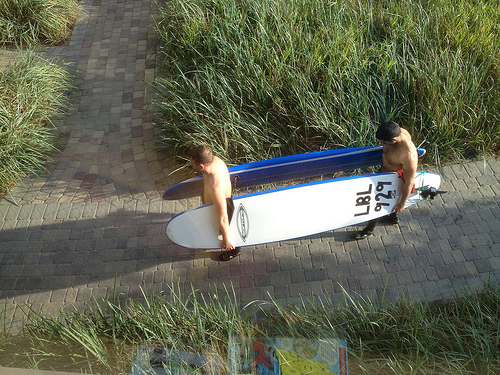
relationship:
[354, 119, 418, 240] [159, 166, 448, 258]
fellas with surfboards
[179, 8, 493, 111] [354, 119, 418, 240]
grass right fellas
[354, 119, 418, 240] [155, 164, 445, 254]
fellas hold surf boards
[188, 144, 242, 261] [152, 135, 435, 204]
dudes hold surf boards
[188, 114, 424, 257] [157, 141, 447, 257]
dudes hold surf boards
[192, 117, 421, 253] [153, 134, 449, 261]
fellas hold surf boards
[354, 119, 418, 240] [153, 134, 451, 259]
fellas held surfboards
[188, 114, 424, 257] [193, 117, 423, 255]
dudes held surfboards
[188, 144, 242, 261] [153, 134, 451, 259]
dudes held surfboards